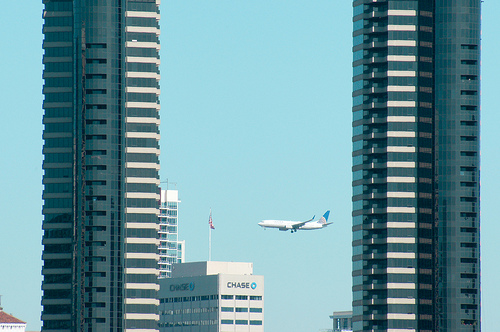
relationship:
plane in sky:
[254, 210, 333, 232] [1, 0, 484, 328]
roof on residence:
[1, 302, 22, 321] [0, 321, 25, 329]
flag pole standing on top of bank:
[206, 206, 216, 260] [156, 259, 266, 330]